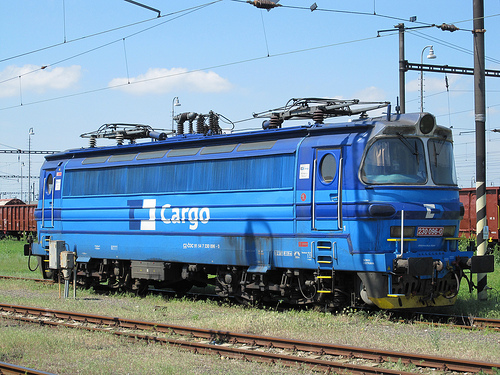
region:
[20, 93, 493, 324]
the train is blue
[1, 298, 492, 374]
the tracks are rusty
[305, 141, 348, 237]
the train has a door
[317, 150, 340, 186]
the door has a round window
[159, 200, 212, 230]
the train says cargo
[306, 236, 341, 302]
the stairs on the train are yellow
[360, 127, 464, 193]
the train has a windshield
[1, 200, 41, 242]
a brown train behind the blue train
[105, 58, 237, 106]
the cloud is white and puffy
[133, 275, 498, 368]
the grass beside the train is long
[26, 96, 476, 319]
A large blue train engine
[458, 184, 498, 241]
A large red train car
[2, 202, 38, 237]
A large red train car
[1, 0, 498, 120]
some overhanging wires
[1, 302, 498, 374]
some rusty railroad tracks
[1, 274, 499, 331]
some rusty railroad tracks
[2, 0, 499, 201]
A clear blue sky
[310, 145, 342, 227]
A door on the train engine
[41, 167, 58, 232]
A door on the train engine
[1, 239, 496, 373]
A grassy landscape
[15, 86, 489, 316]
the train engine is blue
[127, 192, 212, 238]
a logo on the train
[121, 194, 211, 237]
the logo is white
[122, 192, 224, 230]
the logo is dark blue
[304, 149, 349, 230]
the door of the train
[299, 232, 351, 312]
steps up to the door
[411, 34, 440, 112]
a lightpost behind the train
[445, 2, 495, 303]
a pole beside the train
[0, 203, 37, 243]
a car behind the train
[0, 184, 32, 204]
a building behind the car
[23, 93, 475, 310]
a blue train car on railroad tracks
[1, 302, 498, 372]
brown metal railroad tracks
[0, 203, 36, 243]
a red industrial train car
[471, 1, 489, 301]
a grey and white pole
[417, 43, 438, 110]
a lamp on a metal light pole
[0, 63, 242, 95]
clouds in the blue sky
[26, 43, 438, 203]
three utility light poles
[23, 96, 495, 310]
a blue cargo train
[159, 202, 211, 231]
"Cargo" painted on the side of the blue train car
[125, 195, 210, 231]
Cargo logo on the right side of the blue train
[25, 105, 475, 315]
blue train on train tracks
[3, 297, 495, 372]
brown train tracks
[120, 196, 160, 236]
blue and white logo on side of blue train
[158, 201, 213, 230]
white word on side of blue train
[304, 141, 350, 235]
side door on side of train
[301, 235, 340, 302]
yellow steps on side of train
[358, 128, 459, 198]
windshield on front of blue train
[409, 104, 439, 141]
headlight on front of blue train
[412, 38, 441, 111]
tall street lamp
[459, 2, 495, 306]
tall dark pole with stripes on bottom